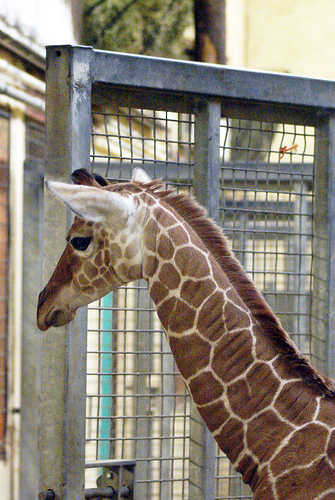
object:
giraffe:
[36, 167, 333, 500]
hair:
[144, 171, 333, 399]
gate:
[38, 44, 331, 498]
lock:
[40, 458, 134, 497]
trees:
[83, 1, 203, 61]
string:
[278, 144, 299, 159]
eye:
[68, 230, 94, 251]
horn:
[71, 167, 107, 189]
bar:
[190, 93, 219, 498]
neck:
[147, 191, 335, 494]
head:
[34, 167, 144, 333]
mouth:
[33, 300, 77, 331]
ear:
[42, 180, 134, 226]